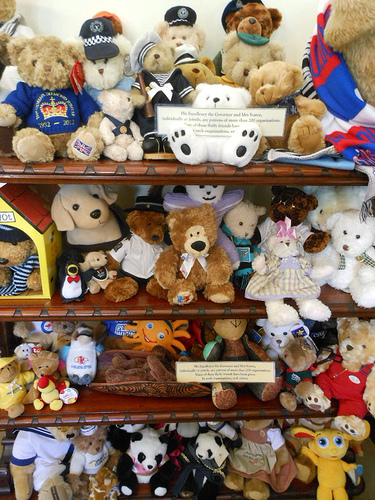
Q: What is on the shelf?
A: Stuffed animals.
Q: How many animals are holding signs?
A: 2.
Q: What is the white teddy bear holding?
A: A sign.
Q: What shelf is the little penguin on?
A: 2nd shelf.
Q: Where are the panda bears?
A: Bottom shelf.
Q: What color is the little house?
A: Yellow.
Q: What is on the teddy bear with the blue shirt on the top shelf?
A: A crown.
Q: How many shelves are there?
A: 4.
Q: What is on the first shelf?
A: Stuffed toys.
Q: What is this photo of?
A: Stuffed animals.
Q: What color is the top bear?
A: White.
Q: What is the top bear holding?
A: A sign.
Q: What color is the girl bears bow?
A: Pink.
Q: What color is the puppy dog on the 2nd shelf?
A: Tan.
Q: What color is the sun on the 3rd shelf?
A: Orange.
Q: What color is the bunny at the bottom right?
A: Yellow.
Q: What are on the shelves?
A: Bears.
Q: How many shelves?
A: 4.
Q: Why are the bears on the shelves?
A: To be displayed.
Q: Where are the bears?
A: On the Shelves.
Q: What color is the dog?
A: Tan.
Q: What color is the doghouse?
A: Yellow.